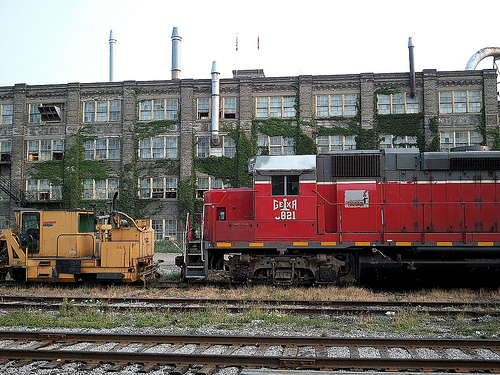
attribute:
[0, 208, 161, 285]
vehicle — yellow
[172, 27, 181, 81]
stack — white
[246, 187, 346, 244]
logo — white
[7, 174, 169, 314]
vehicle — yellow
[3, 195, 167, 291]
machinery — green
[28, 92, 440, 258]
ivy — green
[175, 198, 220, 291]
stairs — black, metal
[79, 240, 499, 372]
tracks — old, rusty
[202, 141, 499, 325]
car — black, red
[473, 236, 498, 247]
line — black, yellow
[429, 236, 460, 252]
line — yellow, black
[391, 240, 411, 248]
line — yellow, black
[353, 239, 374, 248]
line — yellow, black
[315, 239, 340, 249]
line — yellow, black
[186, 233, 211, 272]
stairs — metal 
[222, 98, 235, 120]
window — open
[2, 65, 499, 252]
building — brick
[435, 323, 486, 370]
track — rusted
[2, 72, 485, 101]
cornice — decorative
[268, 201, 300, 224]
lettering — white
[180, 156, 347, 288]
engine — red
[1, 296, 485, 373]
gravel — gray